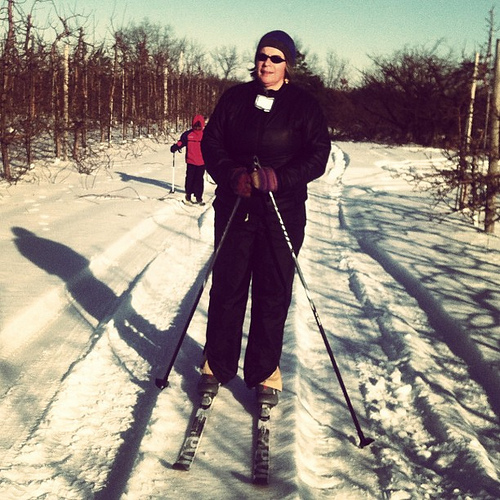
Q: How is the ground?
A: Covered in snow.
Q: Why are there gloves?
A: For warmth.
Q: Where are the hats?
A: On heads.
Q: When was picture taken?
A: Daytime.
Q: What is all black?
A: Suit.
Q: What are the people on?
A: Skis.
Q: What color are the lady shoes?
A: Black.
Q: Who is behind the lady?
A: Child.